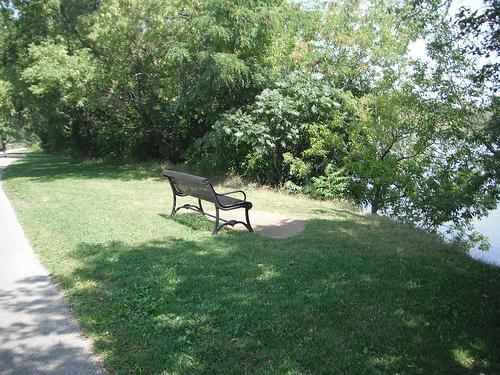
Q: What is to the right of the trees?
A: A body of water.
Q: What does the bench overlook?
A: The water and trees.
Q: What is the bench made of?
A: Metal.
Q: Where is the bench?
A: In the grass.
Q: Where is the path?
A: Behind the bench.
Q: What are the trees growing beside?
A: A body of water.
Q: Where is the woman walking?
A: On a riverside path.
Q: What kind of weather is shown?
A: Sunny.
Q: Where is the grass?
A: On the ground.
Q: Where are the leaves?
A: In the tree.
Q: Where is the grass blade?
A: On the ground.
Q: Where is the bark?
A: On the trees.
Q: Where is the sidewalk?
A: Behind the bench.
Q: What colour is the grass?
A: Green.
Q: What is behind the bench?
A: Sidewalk.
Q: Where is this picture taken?
A: A park.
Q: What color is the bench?
A: Black.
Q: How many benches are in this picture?
A: One.